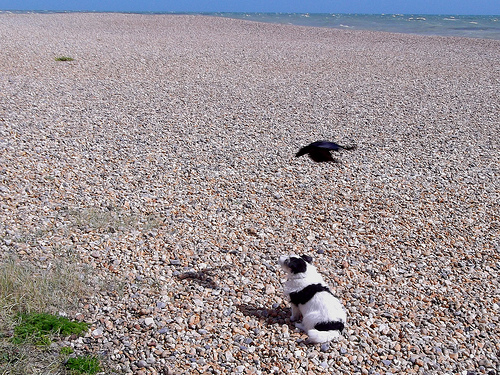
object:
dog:
[278, 253, 348, 344]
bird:
[294, 138, 356, 164]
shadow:
[175, 262, 233, 290]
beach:
[0, 10, 500, 375]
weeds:
[0, 256, 99, 332]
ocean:
[0, 9, 499, 38]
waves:
[211, 11, 500, 30]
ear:
[288, 257, 307, 275]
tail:
[306, 326, 340, 344]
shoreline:
[0, 11, 499, 41]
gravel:
[1, 13, 500, 374]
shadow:
[232, 302, 299, 330]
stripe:
[288, 283, 341, 308]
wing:
[307, 146, 337, 164]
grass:
[13, 310, 92, 346]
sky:
[0, 0, 500, 15]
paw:
[288, 316, 299, 323]